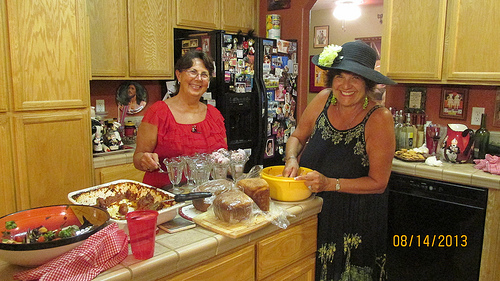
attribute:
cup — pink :
[119, 206, 159, 263]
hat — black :
[311, 43, 391, 88]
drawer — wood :
[252, 214, 321, 277]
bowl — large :
[2, 200, 109, 261]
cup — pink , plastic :
[125, 207, 161, 257]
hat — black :
[312, 31, 395, 83]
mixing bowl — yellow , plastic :
[257, 163, 328, 203]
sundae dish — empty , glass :
[165, 155, 184, 202]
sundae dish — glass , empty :
[178, 152, 199, 185]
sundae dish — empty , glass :
[188, 153, 209, 188]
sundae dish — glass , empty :
[202, 154, 230, 187]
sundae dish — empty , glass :
[224, 149, 249, 183]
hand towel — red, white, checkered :
[6, 222, 141, 279]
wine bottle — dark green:
[474, 104, 495, 155]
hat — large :
[307, 29, 402, 90]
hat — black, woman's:
[312, 34, 403, 88]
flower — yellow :
[316, 36, 350, 78]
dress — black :
[296, 83, 384, 279]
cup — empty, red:
[125, 206, 155, 260]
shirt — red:
[135, 100, 227, 190]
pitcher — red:
[441, 116, 474, 161]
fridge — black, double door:
[190, 36, 336, 168]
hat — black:
[311, 35, 407, 100]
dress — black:
[287, 114, 409, 274]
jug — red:
[420, 125, 494, 177]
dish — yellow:
[257, 156, 344, 209]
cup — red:
[84, 205, 168, 247]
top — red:
[140, 93, 226, 183]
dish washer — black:
[377, 170, 497, 270]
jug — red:
[432, 120, 478, 166]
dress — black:
[297, 96, 397, 274]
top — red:
[142, 100, 218, 180]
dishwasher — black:
[381, 171, 482, 276]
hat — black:
[312, 34, 388, 83]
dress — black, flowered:
[301, 91, 402, 280]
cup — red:
[121, 202, 159, 262]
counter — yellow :
[6, 189, 322, 278]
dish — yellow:
[259, 165, 315, 205]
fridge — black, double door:
[181, 29, 295, 172]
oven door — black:
[379, 176, 499, 279]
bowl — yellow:
[252, 164, 322, 204]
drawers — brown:
[175, 214, 329, 279]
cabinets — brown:
[172, 7, 266, 41]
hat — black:
[304, 34, 387, 84]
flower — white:
[317, 36, 342, 65]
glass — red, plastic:
[128, 205, 158, 257]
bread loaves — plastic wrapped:
[181, 173, 273, 227]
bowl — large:
[6, 193, 115, 280]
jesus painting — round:
[112, 85, 150, 130]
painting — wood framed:
[435, 89, 469, 119]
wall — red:
[270, 5, 497, 155]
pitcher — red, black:
[441, 121, 476, 164]